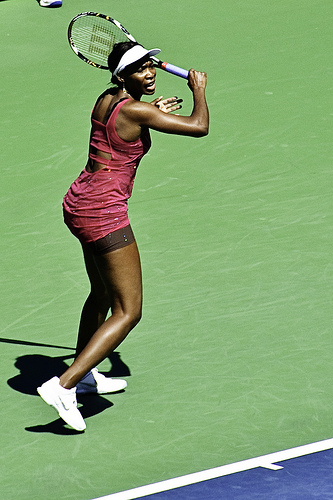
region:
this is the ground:
[228, 198, 320, 327]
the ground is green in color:
[158, 382, 238, 427]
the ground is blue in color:
[248, 472, 285, 492]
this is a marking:
[118, 491, 142, 497]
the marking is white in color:
[119, 490, 135, 496]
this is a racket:
[64, 10, 201, 83]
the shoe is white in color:
[60, 391, 76, 411]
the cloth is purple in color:
[92, 125, 103, 137]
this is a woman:
[30, 39, 230, 423]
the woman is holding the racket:
[62, 11, 217, 132]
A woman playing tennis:
[20, 9, 229, 435]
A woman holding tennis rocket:
[74, 10, 223, 84]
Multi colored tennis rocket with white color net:
[72, 11, 182, 70]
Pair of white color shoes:
[29, 360, 148, 438]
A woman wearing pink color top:
[86, 100, 162, 215]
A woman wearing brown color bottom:
[114, 234, 143, 251]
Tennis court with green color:
[236, 125, 319, 367]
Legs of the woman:
[81, 286, 162, 373]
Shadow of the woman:
[4, 333, 111, 450]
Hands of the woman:
[157, 95, 225, 145]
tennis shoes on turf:
[33, 368, 130, 436]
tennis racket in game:
[63, 12, 196, 72]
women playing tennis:
[36, 13, 266, 431]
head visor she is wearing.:
[98, 38, 183, 75]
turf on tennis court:
[209, 82, 331, 498]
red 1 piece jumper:
[60, 99, 172, 250]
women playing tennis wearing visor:
[102, 39, 172, 88]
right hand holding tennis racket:
[156, 55, 233, 117]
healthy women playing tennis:
[19, 8, 230, 443]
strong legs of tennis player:
[76, 239, 154, 386]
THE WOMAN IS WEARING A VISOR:
[105, 41, 158, 80]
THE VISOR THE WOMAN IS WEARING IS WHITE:
[108, 38, 166, 84]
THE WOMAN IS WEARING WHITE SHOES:
[28, 360, 132, 446]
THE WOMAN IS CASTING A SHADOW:
[1, 330, 144, 444]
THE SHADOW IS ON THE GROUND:
[1, 336, 135, 446]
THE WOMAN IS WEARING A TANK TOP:
[46, 85, 157, 241]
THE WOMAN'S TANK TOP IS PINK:
[59, 87, 155, 244]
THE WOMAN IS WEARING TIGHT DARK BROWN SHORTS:
[64, 206, 153, 257]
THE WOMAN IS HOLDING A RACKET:
[61, 9, 191, 85]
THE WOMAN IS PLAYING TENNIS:
[34, 7, 209, 433]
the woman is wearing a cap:
[110, 42, 157, 78]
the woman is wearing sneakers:
[37, 360, 124, 438]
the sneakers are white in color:
[41, 364, 124, 432]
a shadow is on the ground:
[1, 334, 128, 443]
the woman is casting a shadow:
[3, 330, 145, 442]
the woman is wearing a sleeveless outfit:
[57, 101, 153, 242]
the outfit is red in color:
[62, 96, 151, 248]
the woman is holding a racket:
[62, 9, 207, 92]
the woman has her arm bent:
[146, 66, 212, 140]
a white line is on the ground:
[56, 435, 327, 498]